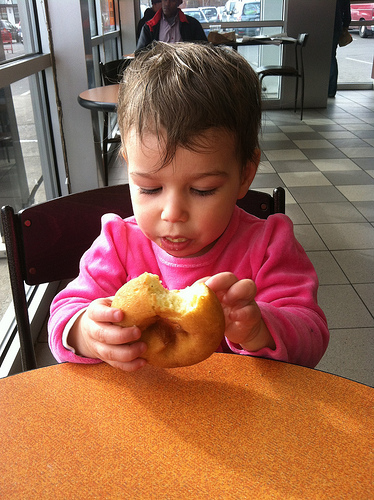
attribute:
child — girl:
[48, 41, 326, 373]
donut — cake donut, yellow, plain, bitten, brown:
[110, 270, 224, 368]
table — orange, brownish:
[0, 350, 373, 499]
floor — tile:
[250, 88, 373, 384]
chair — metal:
[1, 185, 285, 370]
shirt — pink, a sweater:
[48, 213, 331, 368]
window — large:
[1, 1, 63, 364]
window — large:
[88, 4, 122, 86]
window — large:
[178, 1, 283, 95]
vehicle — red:
[347, 1, 374, 37]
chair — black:
[252, 32, 309, 117]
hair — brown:
[117, 38, 262, 174]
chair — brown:
[98, 55, 136, 86]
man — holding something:
[135, 0, 209, 57]